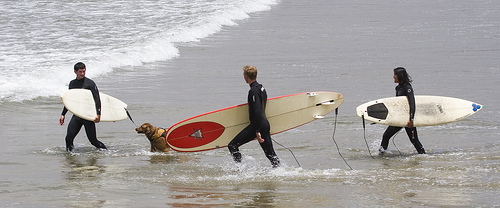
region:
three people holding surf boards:
[33, 37, 490, 197]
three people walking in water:
[0, 44, 465, 203]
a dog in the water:
[128, 107, 177, 174]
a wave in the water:
[0, 7, 256, 114]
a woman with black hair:
[354, 44, 439, 118]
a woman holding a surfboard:
[354, 45, 486, 168]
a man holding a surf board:
[156, 60, 288, 175]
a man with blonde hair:
[234, 57, 271, 99]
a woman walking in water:
[353, 57, 481, 187]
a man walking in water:
[203, 22, 326, 170]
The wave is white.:
[2, 1, 290, 101]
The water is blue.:
[178, 2, 485, 204]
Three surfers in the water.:
[50, 50, 486, 171]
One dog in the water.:
[132, 118, 178, 159]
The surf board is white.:
[351, 90, 484, 130]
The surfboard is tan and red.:
[161, 87, 344, 153]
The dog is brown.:
[130, 119, 174, 157]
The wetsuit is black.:
[221, 82, 286, 172]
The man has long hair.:
[385, 59, 413, 87]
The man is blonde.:
[235, 62, 259, 84]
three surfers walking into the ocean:
[59, 60, 486, 168]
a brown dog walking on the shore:
[136, 122, 178, 155]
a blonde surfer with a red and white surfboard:
[164, 64, 344, 166]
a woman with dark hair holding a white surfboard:
[357, 65, 484, 156]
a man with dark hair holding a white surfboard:
[58, 62, 130, 150]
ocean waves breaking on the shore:
[0, 0, 297, 97]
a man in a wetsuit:
[228, 62, 283, 169]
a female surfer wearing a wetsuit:
[353, 65, 483, 152]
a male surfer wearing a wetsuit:
[58, 59, 130, 151]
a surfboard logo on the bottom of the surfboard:
[188, 127, 205, 139]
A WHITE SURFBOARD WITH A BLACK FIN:
[353, 90, 490, 130]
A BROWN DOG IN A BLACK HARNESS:
[129, 116, 181, 156]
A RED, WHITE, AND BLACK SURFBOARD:
[159, 82, 349, 161]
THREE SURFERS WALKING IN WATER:
[44, 48, 492, 165]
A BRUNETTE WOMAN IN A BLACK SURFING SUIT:
[372, 56, 431, 161]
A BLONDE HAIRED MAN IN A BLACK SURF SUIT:
[224, 53, 289, 169]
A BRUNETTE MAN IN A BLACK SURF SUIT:
[52, 52, 119, 158]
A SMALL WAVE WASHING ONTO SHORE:
[0, 0, 284, 102]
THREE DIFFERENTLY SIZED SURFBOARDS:
[53, 76, 491, 151]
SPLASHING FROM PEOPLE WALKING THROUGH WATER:
[34, 127, 486, 191]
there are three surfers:
[41, 23, 456, 203]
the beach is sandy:
[28, 33, 473, 178]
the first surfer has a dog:
[48, 50, 228, 193]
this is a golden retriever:
[106, 109, 191, 171]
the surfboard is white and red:
[128, 71, 278, 162]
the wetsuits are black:
[14, 30, 499, 180]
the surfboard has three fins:
[288, 47, 390, 185]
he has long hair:
[347, 35, 497, 163]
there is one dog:
[43, 42, 377, 172]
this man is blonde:
[226, 59, 304, 178]